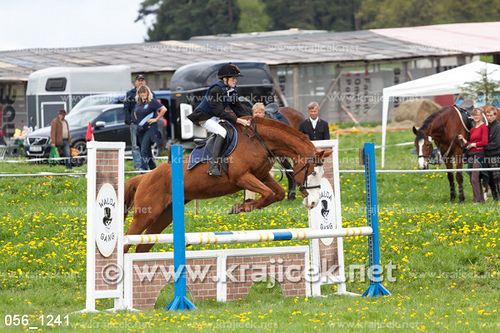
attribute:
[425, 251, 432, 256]
flower — yellow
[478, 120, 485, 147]
sleeve — long 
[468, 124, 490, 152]
shirt — red 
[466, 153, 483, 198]
pants — brown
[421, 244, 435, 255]
flower — yellow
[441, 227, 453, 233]
flower — yellow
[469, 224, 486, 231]
flower — yellow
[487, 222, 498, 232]
flower — yellow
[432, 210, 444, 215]
flower — yellow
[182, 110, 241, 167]
jeans — black 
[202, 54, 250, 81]
hat — black 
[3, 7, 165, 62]
sky — white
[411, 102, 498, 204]
horse — brown, black and white, standing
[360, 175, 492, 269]
flowers — yellow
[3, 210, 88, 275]
flower — yellow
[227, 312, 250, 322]
flower — yellow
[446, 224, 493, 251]
flower — yellow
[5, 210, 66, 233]
flower — yellow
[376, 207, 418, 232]
flower — yellow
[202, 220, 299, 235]
flower — yellow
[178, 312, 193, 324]
flower — yellow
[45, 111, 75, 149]
coat — brown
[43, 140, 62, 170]
sack — green